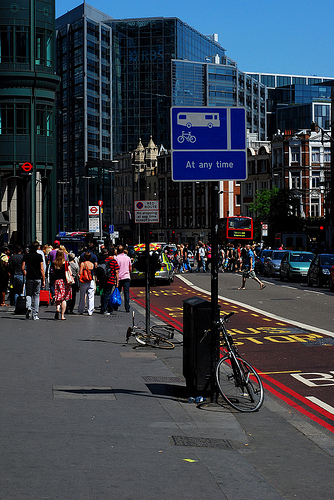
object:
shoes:
[61, 319, 66, 320]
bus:
[225, 216, 253, 245]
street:
[134, 242, 332, 500]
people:
[238, 245, 264, 290]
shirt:
[104, 257, 120, 285]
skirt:
[55, 278, 73, 302]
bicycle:
[200, 311, 265, 413]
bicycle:
[126, 310, 175, 350]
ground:
[1, 271, 333, 498]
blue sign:
[170, 106, 248, 182]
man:
[8, 245, 27, 308]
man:
[115, 245, 133, 312]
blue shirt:
[243, 249, 255, 268]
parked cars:
[307, 254, 333, 288]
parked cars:
[280, 250, 316, 282]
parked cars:
[266, 250, 290, 277]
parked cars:
[257, 248, 265, 273]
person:
[22, 241, 46, 320]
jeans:
[25, 279, 41, 316]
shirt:
[22, 251, 43, 280]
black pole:
[145, 223, 150, 337]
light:
[145, 133, 157, 171]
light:
[134, 135, 147, 174]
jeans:
[115, 278, 130, 309]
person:
[101, 248, 120, 316]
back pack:
[95, 259, 113, 285]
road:
[133, 256, 329, 430]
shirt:
[114, 253, 132, 280]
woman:
[52, 249, 75, 320]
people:
[162, 237, 243, 275]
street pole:
[208, 177, 222, 400]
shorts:
[242, 267, 256, 280]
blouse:
[52, 262, 69, 280]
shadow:
[56, 389, 189, 403]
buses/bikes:
[177, 112, 220, 129]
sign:
[134, 199, 160, 223]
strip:
[123, 270, 334, 435]